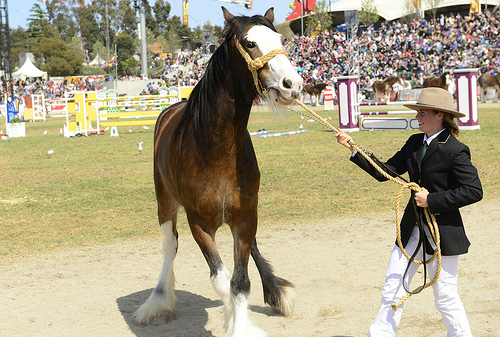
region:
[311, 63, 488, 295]
Brown hat on woman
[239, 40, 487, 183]
Rope is in woman's hand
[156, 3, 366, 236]
Large brown white and black horse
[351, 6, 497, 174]
Stadium full of crowd spectators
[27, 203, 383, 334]
Ground is mostly sand next to grass field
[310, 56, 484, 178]
Racing fence for competition in red and white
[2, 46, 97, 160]
Carnival white tent top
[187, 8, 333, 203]
Horse wearing thick rope halter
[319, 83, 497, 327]
Woman wears white pants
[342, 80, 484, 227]
Black jacket on woman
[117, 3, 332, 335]
Horse in a competition.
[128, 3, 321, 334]
Horse is brown and white.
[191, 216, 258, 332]
Front legs of horse are brown and white.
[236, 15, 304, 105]
Face of horse is white.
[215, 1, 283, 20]
Brown pointy ears of horse.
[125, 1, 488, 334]
Woman pulls a horse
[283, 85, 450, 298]
Rope tied to a horse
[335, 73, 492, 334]
Woman wears black jacket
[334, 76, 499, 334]
Woman wears white pants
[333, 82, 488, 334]
Woman is smiling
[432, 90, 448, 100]
section of a hat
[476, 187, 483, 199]
elbow of a man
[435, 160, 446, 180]
section of a black coat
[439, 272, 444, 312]
section of a white trouser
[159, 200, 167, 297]
back leg of a horse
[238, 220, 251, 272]
front leg of a horse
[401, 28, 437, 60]
section of spectators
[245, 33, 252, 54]
eye of an horse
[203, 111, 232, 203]
front body part of a horse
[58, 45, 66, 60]
leaves of a tree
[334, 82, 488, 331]
A woman in a tan hat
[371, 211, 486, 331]
White pants on a woman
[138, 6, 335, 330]
A brown horse with white on its head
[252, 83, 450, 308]
A rope tied to a horse halter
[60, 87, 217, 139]
Steeplechase obstacles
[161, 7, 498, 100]
A large audience in the stands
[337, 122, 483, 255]
A black coat on a woman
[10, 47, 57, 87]
A pointed white tent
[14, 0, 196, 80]
Trees in the background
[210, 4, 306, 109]
A halter on a horse's head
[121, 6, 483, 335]
woman holding show horse by a rope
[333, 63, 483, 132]
red-colored horse jump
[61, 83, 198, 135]
yellow-colored horse jump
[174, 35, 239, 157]
horse's black mane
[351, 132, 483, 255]
woman's black riding jacket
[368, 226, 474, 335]
woman's white pants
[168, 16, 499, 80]
crowd in stands at horse show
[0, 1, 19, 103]
metal scaffold on left side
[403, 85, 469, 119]
hat with wide brim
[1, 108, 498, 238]
grassy part of arena